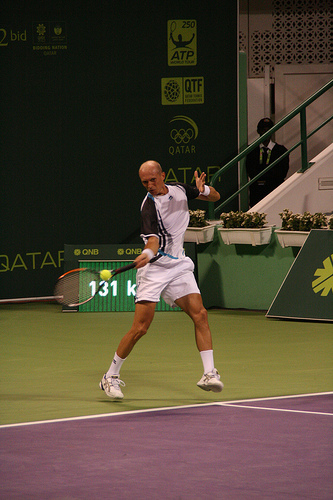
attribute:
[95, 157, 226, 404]
man — playing tennis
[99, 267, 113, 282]
tennis ball — airborne, yellow, green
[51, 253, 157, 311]
racquet — red, black, orange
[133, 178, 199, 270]
shirt — black, white, white blue, multicolored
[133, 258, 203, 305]
shorts — white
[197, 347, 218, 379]
sock — white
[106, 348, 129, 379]
sock — white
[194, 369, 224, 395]
tennis shoe — white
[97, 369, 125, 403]
tennis shoe — white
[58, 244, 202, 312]
sign — black green, white, green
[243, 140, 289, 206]
suit — black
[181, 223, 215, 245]
planter — white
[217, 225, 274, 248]
planter — white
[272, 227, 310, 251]
planter — white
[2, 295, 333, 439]
section — green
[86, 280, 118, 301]
number — white, 131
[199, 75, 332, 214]
railing — green, metal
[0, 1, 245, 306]
wall — dark green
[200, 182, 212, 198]
wrist band — white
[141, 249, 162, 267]
wrist band — white